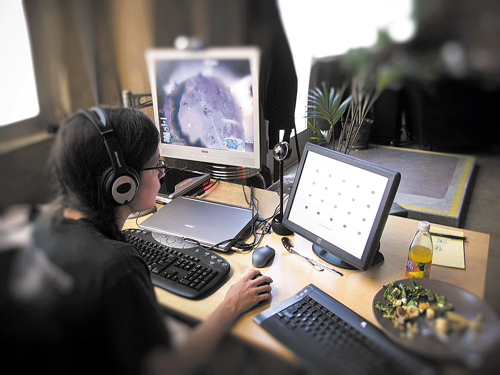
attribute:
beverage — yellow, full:
[381, 225, 435, 289]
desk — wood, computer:
[104, 116, 474, 346]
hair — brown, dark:
[68, 131, 101, 174]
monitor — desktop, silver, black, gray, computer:
[123, 19, 285, 196]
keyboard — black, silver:
[107, 204, 251, 320]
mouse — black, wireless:
[236, 235, 285, 274]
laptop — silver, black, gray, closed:
[124, 162, 262, 282]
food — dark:
[366, 260, 492, 348]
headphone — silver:
[88, 159, 134, 222]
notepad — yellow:
[418, 216, 461, 247]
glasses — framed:
[120, 135, 179, 190]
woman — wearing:
[0, 50, 256, 360]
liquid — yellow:
[400, 228, 431, 286]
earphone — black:
[101, 153, 150, 207]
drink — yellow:
[396, 212, 446, 286]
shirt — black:
[25, 191, 176, 353]